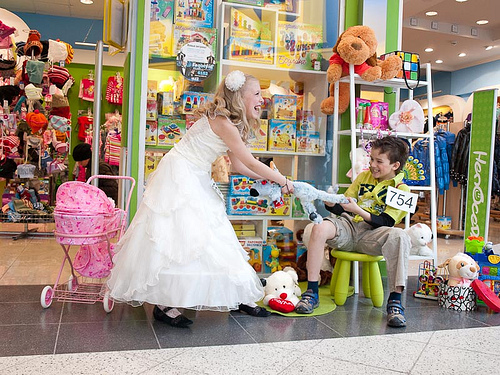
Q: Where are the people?
A: Toy Store.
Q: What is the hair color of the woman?
A: Blonde.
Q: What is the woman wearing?
A: Dress.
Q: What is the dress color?
A: White.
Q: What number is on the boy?
A: 754.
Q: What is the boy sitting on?
A: Stool.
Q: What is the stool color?
A: Green.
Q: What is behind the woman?
A: Stroller.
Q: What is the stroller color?
A: Pink.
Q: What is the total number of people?
A: 2.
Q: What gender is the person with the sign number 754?
A: Male.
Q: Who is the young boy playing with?
A: Girl.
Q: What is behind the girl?
A: Stroller.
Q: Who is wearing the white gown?
A: Girl.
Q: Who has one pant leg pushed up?
A: Boy.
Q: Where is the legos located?
A: Behind kids.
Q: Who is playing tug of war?
A: Girl and boy.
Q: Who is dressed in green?
A: Boy.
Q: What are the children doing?
A: Playing.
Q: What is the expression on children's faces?
A: Enjoyment.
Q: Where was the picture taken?
A: In a toy store.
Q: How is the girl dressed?
A: In a white dress.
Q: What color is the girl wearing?
A: White.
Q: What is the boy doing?
A: Sitting down.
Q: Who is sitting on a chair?
A: A boy.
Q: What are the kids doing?
A: Pulling an animal.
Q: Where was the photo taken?
A: In front of a store.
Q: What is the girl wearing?
A: A dress.